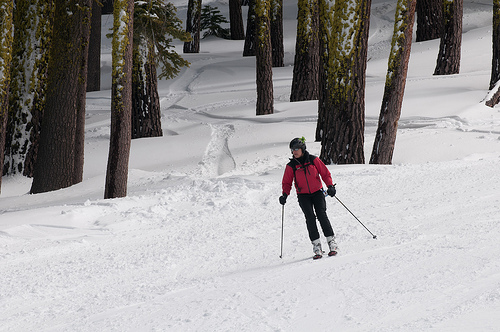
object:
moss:
[111, 1, 132, 101]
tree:
[101, 1, 133, 199]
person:
[278, 137, 340, 260]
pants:
[296, 188, 334, 240]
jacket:
[280, 152, 335, 195]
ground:
[0, 0, 499, 331]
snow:
[0, 2, 497, 331]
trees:
[432, 1, 463, 77]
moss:
[323, 1, 366, 102]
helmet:
[289, 138, 305, 150]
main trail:
[2, 163, 499, 331]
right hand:
[277, 194, 287, 205]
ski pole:
[276, 202, 285, 262]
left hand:
[327, 185, 337, 198]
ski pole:
[333, 194, 379, 241]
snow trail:
[80, 0, 500, 181]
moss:
[252, 0, 272, 44]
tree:
[253, 0, 274, 115]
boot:
[325, 236, 341, 257]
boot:
[310, 240, 324, 259]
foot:
[329, 246, 340, 257]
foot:
[313, 249, 324, 259]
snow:
[116, 9, 126, 49]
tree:
[368, 1, 419, 165]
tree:
[28, 0, 88, 193]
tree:
[290, 0, 321, 101]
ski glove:
[276, 193, 287, 204]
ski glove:
[326, 183, 337, 198]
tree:
[131, 0, 195, 139]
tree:
[9, 2, 56, 178]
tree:
[413, 1, 447, 42]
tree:
[182, 0, 201, 54]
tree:
[228, 0, 244, 40]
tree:
[315, 0, 370, 164]